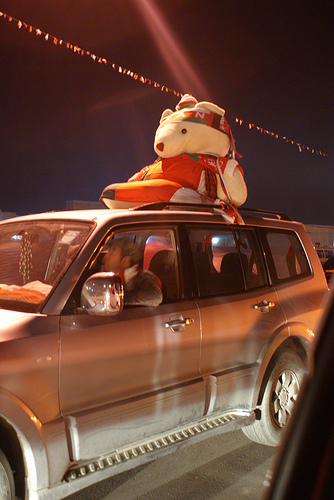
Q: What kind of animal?
A: Stuffed.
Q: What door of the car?
A: Left.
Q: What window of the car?
A: Front.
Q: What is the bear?
A: Teddy.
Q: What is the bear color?
A: White.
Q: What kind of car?
A: Suv.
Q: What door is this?
A: Driver.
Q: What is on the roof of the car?
A: A teddy bear.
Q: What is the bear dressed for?
A: Christmas.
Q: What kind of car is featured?
A: An SUV.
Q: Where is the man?
A: In the driver's seat.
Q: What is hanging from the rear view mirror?
A: Green, white and red decorations.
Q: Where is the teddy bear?
A: On the roof of the car.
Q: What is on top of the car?
A: Bear.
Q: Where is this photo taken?
A: On a street.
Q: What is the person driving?
A: A car.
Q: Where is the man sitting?
A: Behind the wheel of the car.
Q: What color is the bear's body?
A: White.